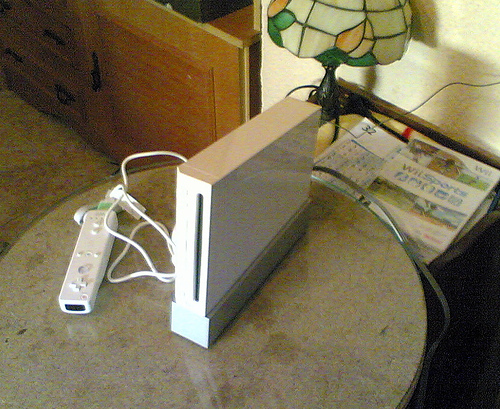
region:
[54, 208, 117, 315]
white wii remote on a table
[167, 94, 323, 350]
Nintendo Wii on a table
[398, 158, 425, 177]
gray print on a booklet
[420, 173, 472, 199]
light blue print on a booklet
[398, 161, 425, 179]
text on a booklet reading Wii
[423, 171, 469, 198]
blue text on a booklet reading Sports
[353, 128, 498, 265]
booklet on a table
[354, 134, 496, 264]
Wii sports booklet on a table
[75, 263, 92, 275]
round clear button a wii remote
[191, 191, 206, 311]
slot on Wii console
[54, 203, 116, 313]
a wii remote control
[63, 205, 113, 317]
the wii remote control is white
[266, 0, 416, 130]
a lamp on the table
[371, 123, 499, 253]
a book on the table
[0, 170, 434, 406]
the table is round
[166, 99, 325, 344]
the game bow is unplugged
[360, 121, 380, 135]
the number 32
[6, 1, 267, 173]
a brown cabinet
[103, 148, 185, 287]
the cord is tangled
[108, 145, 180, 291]
the cord is white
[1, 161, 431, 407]
round table with wii game system on it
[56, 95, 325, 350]
Wii game system on round table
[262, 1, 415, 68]
stained glass lamp shade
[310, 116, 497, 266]
calander on chair next to table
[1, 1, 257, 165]
dresser next to wall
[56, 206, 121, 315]
controller of Wii on table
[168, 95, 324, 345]
Wii console sitting on round table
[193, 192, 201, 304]
disk slit on Wii console box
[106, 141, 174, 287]
wire of controller of we game station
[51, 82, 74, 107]
handle on dresser draw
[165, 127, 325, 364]
WHITE NINTENDO WII ON TABLE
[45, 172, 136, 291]
WHITE WII REMOTE ON TABLE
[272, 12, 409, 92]
LAMP BEHIND NINTENDO WII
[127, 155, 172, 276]
WHITE WIRES AROUND REMOTE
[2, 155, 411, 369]
TAN SURFACE OF ROUND TABLE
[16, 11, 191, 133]
WOOD CABINETS ON LEFT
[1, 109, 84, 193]
TAN CARPET ON FLOOR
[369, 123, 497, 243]
WHITE BOOK ON RIGHT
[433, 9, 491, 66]
CREAM COLORED WALL BEHIND LAMP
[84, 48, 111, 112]
BLACK HANDLES ON WOOD CABINET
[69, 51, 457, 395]
a wii on a table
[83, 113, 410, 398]
a white wii on a table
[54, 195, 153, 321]
a wii remote on a table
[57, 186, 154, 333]
a white wii remote on a table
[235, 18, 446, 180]
a lamp on a table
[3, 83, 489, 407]
a table with a wii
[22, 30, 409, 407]
a table with a white wii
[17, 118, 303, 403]
a table with a remote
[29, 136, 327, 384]
a table with a white wii remote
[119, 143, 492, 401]
wii on a small table